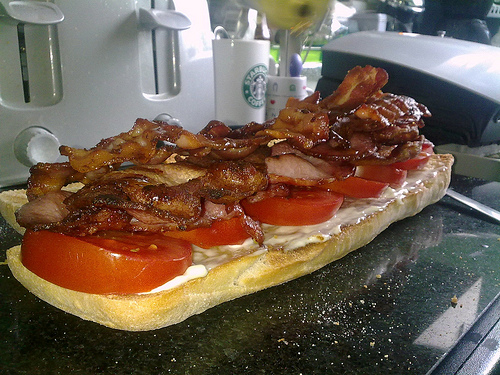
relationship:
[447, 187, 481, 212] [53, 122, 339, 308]
utensil next to sandwich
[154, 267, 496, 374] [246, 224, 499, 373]
crumbs are on counter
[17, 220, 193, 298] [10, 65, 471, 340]
tomato on sandwich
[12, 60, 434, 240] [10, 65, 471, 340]
bacon on sandwich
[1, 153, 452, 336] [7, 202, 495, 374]
bread on counter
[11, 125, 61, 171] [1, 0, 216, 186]
knob on toaster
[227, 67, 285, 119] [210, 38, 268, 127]
logo on coffee mug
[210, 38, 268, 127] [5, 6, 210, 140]
coffee mug next to toaster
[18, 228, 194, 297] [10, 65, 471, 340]
tomatoe are on sandwich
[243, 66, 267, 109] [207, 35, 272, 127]
logo on mug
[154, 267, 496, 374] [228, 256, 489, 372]
crumbs are on counter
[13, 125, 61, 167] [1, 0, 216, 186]
knob on toaster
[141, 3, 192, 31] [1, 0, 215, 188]
handle on toaster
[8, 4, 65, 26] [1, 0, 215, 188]
lever on toaster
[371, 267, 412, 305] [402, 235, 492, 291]
crumbs on counter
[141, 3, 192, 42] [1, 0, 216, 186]
handle on toaster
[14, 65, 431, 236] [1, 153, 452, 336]
bacon on bread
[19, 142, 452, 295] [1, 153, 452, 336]
tomato on bread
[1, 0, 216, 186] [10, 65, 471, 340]
toaster behind sandwich